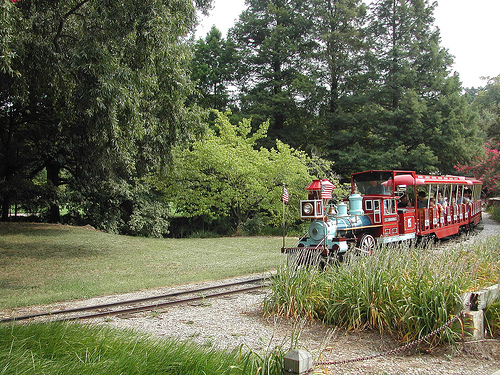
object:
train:
[275, 169, 485, 260]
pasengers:
[409, 186, 431, 211]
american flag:
[280, 184, 289, 205]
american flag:
[317, 180, 332, 200]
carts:
[393, 170, 487, 243]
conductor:
[358, 174, 388, 198]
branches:
[70, 61, 135, 153]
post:
[458, 285, 480, 335]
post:
[277, 344, 309, 374]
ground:
[159, 302, 258, 330]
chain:
[300, 311, 462, 367]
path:
[313, 363, 497, 372]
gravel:
[127, 313, 192, 334]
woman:
[394, 170, 416, 210]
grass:
[0, 334, 89, 373]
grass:
[288, 255, 437, 313]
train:
[278, 160, 492, 256]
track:
[2, 224, 498, 329]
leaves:
[3, 1, 265, 193]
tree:
[2, 2, 220, 234]